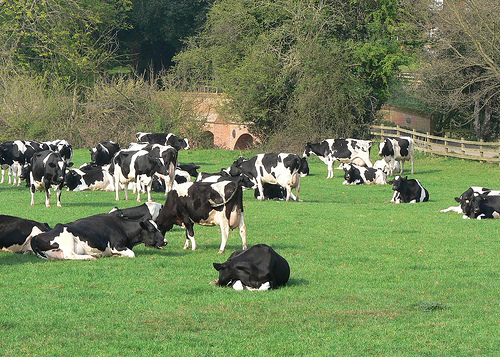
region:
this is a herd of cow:
[0, 115, 419, 317]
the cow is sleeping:
[213, 234, 303, 294]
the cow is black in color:
[254, 254, 280, 276]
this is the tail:
[212, 180, 234, 213]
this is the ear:
[206, 263, 223, 274]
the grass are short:
[311, 208, 402, 278]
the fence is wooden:
[451, 133, 481, 160]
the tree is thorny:
[445, 9, 498, 94]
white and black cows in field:
[6, 107, 498, 311]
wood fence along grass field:
[368, 118, 499, 168]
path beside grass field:
[382, 124, 499, 169]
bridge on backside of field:
[168, 87, 276, 145]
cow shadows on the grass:
[133, 222, 287, 265]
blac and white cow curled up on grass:
[207, 240, 285, 293]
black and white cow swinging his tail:
[150, 177, 248, 250]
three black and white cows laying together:
[2, 203, 161, 268]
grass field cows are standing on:
[7, 144, 499, 356]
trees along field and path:
[5, 6, 488, 153]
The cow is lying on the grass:
[215, 245, 293, 292]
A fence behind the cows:
[366, 123, 498, 159]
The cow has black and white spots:
[240, 153, 291, 182]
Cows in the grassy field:
[1, 129, 499, 293]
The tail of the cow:
[209, 182, 241, 211]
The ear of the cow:
[209, 258, 225, 270]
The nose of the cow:
[158, 237, 168, 246]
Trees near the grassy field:
[0, 5, 389, 132]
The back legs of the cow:
[218, 219, 253, 254]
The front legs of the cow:
[179, 218, 198, 251]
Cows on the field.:
[56, 88, 313, 312]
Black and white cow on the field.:
[178, 211, 375, 318]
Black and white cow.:
[196, 216, 306, 313]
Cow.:
[23, 196, 168, 286]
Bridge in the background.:
[168, 84, 458, 200]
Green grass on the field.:
[273, 124, 441, 332]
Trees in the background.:
[200, 24, 445, 161]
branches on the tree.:
[43, 27, 195, 169]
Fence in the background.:
[354, 94, 484, 180]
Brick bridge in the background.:
[181, 87, 323, 177]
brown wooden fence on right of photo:
[434, 129, 491, 156]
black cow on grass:
[210, 247, 312, 300]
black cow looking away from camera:
[202, 242, 310, 306]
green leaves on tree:
[340, 6, 424, 78]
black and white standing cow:
[161, 179, 263, 241]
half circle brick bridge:
[212, 113, 286, 153]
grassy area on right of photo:
[395, 297, 497, 342]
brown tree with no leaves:
[443, 9, 498, 109]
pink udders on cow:
[278, 178, 313, 190]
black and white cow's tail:
[214, 178, 255, 218]